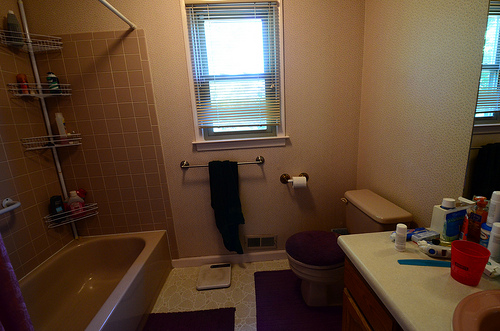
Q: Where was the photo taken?
A: Bathroom.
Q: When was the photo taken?
A: In the daytime.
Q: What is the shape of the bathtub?
A: Rectangle.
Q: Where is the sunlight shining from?
A: Window.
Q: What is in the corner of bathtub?
A: Shower organizer.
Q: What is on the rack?
A: Towel.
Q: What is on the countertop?
A: Toiletries.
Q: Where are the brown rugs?
A: Floor.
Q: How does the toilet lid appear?
A: Closed.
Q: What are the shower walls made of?
A: Tile.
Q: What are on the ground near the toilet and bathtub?
A: Rugs.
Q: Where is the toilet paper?
A: On the roll near the toilet.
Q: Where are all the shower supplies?
A: On the shower rack.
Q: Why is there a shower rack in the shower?
A: To hold supplies.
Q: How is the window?
A: Closed.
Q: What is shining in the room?
A: Sunlight.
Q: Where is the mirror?
A: Opposite the bathtub.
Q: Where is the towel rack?
A: Under the window.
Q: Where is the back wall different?
A: In the shower.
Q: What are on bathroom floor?
A: Rugs.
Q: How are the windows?
A: Covered.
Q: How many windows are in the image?
A: 1.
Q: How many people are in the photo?
A: 0.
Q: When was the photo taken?
A: Daytime.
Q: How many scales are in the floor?
A: 1.